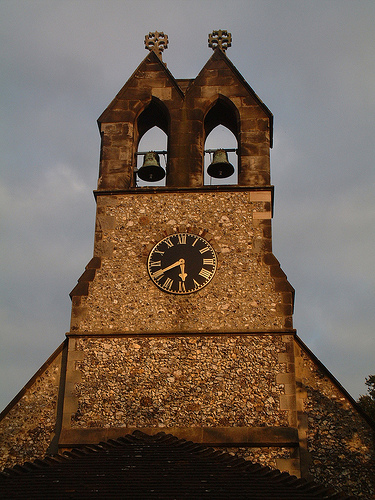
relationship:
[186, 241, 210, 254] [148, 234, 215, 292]
metal clock face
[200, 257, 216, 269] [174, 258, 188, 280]
numeral in golden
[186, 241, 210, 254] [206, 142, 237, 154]
metal from pole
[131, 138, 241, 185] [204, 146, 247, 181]
two metal bells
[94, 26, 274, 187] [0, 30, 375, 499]
top of belfry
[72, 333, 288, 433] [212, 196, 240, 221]
wall of colors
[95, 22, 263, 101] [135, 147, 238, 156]
roof of beam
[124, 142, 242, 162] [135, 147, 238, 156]
beam across beam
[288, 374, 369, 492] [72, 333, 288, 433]
shadows on wall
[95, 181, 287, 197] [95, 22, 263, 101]
shingles of roof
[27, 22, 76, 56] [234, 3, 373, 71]
cloudy blue sky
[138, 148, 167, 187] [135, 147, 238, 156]
bell on beam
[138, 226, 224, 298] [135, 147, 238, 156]
clock on beam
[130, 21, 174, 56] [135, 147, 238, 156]
decor on beam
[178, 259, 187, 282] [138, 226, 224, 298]
golden on clock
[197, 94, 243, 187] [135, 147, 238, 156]
arched on beam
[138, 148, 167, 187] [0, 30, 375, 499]
bell in belfry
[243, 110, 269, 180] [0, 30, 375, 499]
brick clock belfry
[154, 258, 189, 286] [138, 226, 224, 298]
5:40 on clock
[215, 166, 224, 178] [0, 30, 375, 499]
shaft on belfry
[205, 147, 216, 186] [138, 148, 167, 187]
rope of bell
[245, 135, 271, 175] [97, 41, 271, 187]
block constructed belfry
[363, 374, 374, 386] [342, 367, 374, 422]
leaf covered tree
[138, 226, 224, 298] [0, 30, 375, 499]
clock on belfry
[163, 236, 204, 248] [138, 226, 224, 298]
numerals on clock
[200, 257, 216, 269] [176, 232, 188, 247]
numeral for twelve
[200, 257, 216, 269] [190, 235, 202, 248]
numeral for one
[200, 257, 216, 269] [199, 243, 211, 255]
numeral for two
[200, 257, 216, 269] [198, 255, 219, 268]
numeral for three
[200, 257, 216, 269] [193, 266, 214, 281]
numeral for four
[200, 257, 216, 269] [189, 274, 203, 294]
numeral for five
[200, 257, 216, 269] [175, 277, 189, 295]
numeral for six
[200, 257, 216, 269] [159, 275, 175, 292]
numeral for seven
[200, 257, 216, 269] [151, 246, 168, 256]
numeral for ten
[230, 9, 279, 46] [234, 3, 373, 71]
cloud in sky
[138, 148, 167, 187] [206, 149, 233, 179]
bell next to bell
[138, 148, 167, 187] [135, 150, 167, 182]
bell next to bell